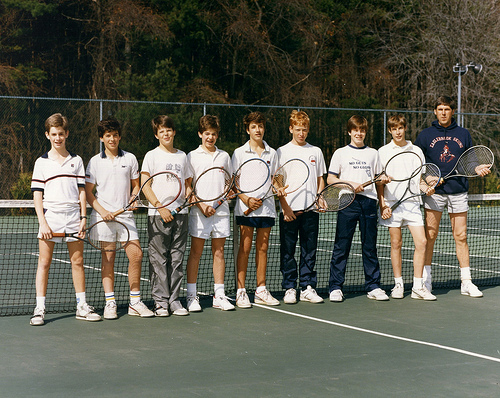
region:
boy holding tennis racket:
[22, 91, 99, 340]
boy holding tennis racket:
[85, 121, 144, 311]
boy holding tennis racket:
[143, 102, 200, 332]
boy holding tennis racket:
[185, 101, 232, 327]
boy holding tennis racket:
[239, 102, 294, 330]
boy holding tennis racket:
[281, 102, 334, 332]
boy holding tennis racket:
[330, 97, 387, 289]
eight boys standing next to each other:
[33, 109, 429, 329]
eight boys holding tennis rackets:
[31, 111, 421, 329]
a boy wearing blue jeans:
[275, 198, 322, 298]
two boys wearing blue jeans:
[278, 188, 380, 299]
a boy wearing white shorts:
[24, 206, 86, 320]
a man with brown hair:
[433, 97, 456, 118]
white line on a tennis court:
[291, 307, 498, 377]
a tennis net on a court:
[0, 187, 38, 327]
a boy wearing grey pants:
[147, 207, 188, 309]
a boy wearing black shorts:
[234, 209, 278, 233]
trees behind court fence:
[1, 2, 498, 193]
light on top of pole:
[453, 60, 484, 121]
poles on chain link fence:
[1, 93, 498, 215]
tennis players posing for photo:
[30, 98, 494, 325]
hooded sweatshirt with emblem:
[421, 121, 473, 194]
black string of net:
[0, 200, 499, 312]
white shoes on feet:
[31, 280, 483, 326]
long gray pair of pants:
[147, 211, 187, 308]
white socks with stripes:
[103, 289, 143, 305]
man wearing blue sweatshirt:
[420, 85, 487, 311]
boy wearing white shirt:
[380, 110, 440, 309]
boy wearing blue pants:
[330, 115, 387, 314]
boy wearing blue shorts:
[239, 108, 287, 308]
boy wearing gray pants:
[137, 115, 195, 317]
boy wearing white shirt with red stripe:
[29, 107, 96, 318]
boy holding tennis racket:
[87, 113, 148, 319]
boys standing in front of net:
[27, 85, 490, 310]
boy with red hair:
[281, 101, 337, 316]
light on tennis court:
[446, 49, 479, 150]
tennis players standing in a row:
[32, 97, 493, 324]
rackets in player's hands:
[45, 144, 493, 249]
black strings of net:
[0, 199, 498, 313]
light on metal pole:
[453, 62, 483, 123]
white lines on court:
[0, 208, 497, 396]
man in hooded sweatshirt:
[417, 97, 475, 192]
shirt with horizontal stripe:
[31, 152, 84, 211]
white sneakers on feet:
[31, 279, 483, 325]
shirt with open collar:
[232, 143, 275, 216]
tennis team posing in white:
[41, 103, 499, 317]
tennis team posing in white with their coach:
[37, 85, 484, 316]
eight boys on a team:
[25, 106, 427, 318]